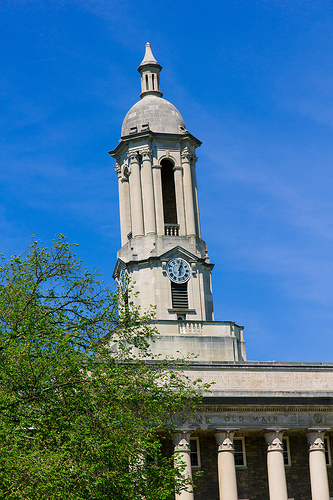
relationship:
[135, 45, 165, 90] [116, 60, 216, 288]
part of pillar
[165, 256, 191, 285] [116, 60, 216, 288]
clock on pillar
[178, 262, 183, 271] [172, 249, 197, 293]
hands on clock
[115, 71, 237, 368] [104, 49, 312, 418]
tower on building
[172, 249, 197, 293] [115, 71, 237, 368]
clock on tower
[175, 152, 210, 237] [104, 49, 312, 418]
column on building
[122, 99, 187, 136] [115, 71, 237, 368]
dome of tower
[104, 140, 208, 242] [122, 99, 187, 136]
columns under dome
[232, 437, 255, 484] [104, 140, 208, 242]
windows behind columns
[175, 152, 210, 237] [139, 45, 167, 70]
column on top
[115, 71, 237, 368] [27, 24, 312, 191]
tower in sky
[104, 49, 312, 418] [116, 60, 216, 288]
building has pillar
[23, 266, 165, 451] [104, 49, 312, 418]
trees in building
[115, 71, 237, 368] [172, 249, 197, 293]
tower has clock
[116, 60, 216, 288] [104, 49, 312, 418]
pillar on building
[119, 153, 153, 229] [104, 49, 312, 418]
pillars on building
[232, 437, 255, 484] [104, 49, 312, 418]
windows in building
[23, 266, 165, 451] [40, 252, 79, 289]
trees have branches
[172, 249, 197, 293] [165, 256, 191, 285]
clock has clock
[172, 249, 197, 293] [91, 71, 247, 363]
clock on tower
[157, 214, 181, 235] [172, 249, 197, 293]
platform in clock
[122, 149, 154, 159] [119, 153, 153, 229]
detailing on pillars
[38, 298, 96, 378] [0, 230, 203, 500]
leaves of a trees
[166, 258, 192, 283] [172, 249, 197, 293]
face of a clock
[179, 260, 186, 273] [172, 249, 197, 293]
hands of a clock